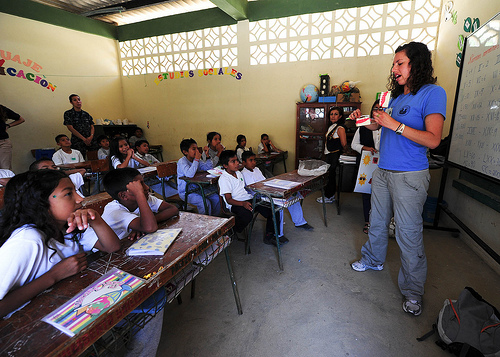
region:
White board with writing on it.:
[449, 11, 496, 181]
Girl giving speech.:
[349, 40, 449, 322]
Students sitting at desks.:
[1, 127, 274, 305]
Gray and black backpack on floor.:
[420, 279, 495, 354]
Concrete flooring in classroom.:
[223, 242, 353, 352]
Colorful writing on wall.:
[2, 42, 58, 101]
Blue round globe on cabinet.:
[297, 83, 322, 103]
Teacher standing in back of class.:
[0, 90, 30, 169]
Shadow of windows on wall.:
[117, 0, 457, 79]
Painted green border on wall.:
[1, 0, 418, 42]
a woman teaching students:
[364, 36, 458, 235]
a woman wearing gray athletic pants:
[358, 155, 442, 323]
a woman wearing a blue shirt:
[373, 75, 449, 171]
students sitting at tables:
[1, 136, 194, 338]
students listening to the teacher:
[161, 108, 274, 218]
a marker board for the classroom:
[455, 29, 499, 172]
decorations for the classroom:
[0, 41, 62, 101]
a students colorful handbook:
[40, 273, 148, 338]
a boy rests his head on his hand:
[103, 161, 177, 240]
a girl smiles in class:
[102, 131, 143, 172]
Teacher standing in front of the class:
[348, 38, 449, 320]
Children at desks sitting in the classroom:
[1, 130, 282, 317]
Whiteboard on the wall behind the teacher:
[444, 8, 498, 180]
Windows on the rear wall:
[112, 1, 449, 79]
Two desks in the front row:
[0, 158, 336, 356]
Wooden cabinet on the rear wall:
[290, 97, 364, 179]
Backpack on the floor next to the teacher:
[415, 281, 497, 354]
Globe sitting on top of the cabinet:
[294, 79, 321, 106]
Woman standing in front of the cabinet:
[317, 103, 351, 205]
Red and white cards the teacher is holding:
[352, 86, 394, 133]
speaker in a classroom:
[349, 36, 431, 311]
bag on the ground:
[428, 279, 499, 349]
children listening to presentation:
[12, 132, 298, 275]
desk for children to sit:
[251, 168, 333, 253]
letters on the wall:
[146, 69, 247, 91]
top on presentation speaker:
[374, 82, 449, 169]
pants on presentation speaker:
[359, 165, 430, 295]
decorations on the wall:
[443, 2, 478, 74]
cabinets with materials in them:
[286, 103, 353, 187]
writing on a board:
[454, 72, 495, 144]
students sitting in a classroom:
[57, 135, 308, 224]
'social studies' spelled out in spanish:
[149, 66, 243, 86]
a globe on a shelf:
[299, 85, 318, 103]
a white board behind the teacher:
[436, 26, 497, 183]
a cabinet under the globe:
[296, 97, 360, 182]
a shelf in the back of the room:
[93, 118, 139, 140]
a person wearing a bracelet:
[56, 93, 96, 150]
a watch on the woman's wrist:
[388, 120, 414, 142]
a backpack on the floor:
[428, 282, 498, 355]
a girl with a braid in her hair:
[0, 170, 91, 296]